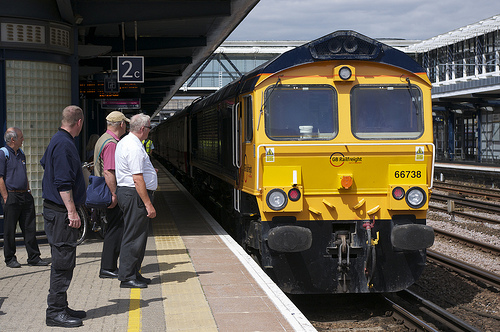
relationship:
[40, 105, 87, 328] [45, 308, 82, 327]
commuters in feet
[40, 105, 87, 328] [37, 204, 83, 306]
commuters in pant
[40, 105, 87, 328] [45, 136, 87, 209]
commuters in shirt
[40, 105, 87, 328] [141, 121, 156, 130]
commuters in sunglasses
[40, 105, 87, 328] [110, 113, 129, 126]
commuters in hat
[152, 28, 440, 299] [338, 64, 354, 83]
train has head light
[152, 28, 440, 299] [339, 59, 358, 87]
train has headlight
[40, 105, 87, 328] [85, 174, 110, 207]
commuters with bag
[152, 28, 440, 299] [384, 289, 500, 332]
train on rails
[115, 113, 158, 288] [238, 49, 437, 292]
man waiting for train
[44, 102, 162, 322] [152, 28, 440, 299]
commuters waiting on an arriving train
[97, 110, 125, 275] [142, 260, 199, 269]
man has shadow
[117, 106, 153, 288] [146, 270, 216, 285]
man has shadow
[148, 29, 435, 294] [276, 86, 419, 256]
train has front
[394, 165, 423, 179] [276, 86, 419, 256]
number in front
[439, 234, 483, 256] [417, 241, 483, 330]
gravel between tracks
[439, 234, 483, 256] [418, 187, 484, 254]
gravel between tracks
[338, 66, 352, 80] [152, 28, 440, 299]
head light on train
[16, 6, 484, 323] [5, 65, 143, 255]
depot has front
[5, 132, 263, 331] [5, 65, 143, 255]
sidewalk in front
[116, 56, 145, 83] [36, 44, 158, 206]
sign in front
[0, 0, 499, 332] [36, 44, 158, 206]
depot has front